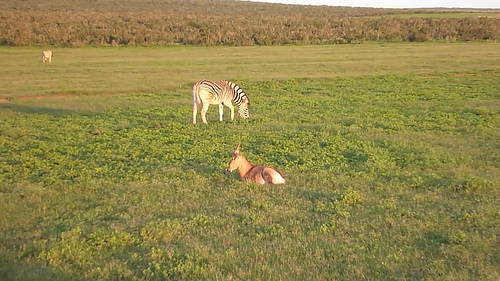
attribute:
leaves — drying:
[373, 10, 418, 40]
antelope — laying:
[222, 138, 295, 190]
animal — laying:
[182, 76, 253, 127]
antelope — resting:
[207, 133, 294, 188]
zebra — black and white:
[194, 77, 259, 134]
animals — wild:
[2, 48, 292, 223]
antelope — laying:
[224, 138, 286, 187]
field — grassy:
[0, 0, 499, 278]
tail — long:
[192, 86, 201, 103]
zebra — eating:
[190, 78, 250, 126]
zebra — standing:
[191, 80, 251, 121]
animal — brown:
[225, 139, 292, 185]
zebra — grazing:
[188, 74, 254, 127]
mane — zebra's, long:
[226, 81, 251, 105]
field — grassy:
[6, 69, 476, 259]